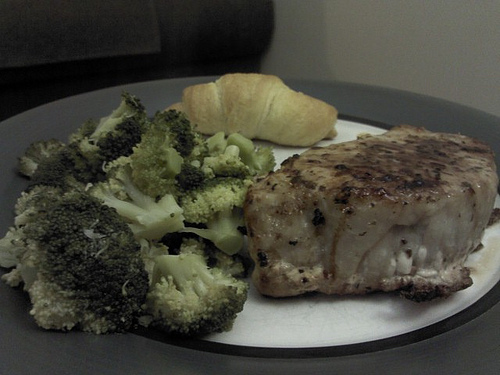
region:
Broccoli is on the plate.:
[5, 87, 280, 348]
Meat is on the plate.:
[245, 106, 495, 316]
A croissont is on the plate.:
[150, 60, 385, 140]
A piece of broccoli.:
[20, 180, 185, 330]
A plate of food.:
[0, 70, 497, 370]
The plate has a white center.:
[70, 120, 485, 335]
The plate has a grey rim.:
[0, 56, 495, 367]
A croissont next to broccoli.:
[100, 65, 335, 170]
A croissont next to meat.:
[205, 71, 467, 211]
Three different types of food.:
[11, 72, 481, 350]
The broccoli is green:
[33, 149, 234, 311]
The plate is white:
[231, 285, 358, 369]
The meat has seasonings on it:
[263, 134, 440, 293]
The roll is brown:
[176, 67, 333, 158]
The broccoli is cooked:
[38, 150, 192, 285]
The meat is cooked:
[320, 150, 475, 321]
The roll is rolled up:
[168, 60, 332, 155]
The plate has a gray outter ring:
[13, 299, 105, 371]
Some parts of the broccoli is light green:
[36, 181, 280, 323]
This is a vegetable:
[27, 121, 228, 326]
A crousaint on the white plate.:
[150, 59, 345, 147]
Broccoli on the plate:
[51, 126, 255, 301]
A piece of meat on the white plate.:
[248, 140, 496, 297]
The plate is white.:
[143, 193, 426, 370]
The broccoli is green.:
[87, 111, 268, 318]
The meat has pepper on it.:
[328, 136, 443, 214]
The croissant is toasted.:
[161, 61, 351, 161]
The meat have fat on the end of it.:
[241, 183, 316, 290]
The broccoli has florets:
[47, 213, 132, 328]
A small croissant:
[173, 68, 340, 145]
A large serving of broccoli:
[11, 117, 265, 339]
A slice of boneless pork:
[249, 128, 498, 297]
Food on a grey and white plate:
[2, 79, 499, 374]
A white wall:
[288, 9, 499, 88]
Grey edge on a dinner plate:
[3, 68, 498, 370]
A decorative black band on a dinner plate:
[181, 331, 436, 359]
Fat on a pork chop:
[426, 195, 495, 280]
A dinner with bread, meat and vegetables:
[27, 74, 499, 348]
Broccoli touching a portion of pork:
[220, 143, 300, 305]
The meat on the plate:
[238, 110, 498, 325]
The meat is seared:
[237, 118, 497, 303]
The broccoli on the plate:
[10, 88, 270, 348]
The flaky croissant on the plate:
[158, 64, 342, 145]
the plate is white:
[68, 101, 498, 355]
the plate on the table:
[76, 109, 498, 364]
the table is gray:
[8, 65, 498, 374]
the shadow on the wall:
[265, 4, 350, 84]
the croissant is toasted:
[155, 64, 368, 152]